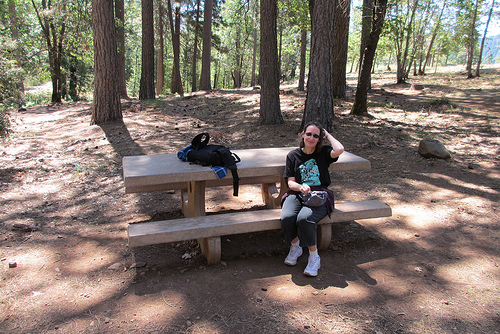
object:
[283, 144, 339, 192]
shirt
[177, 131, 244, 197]
backpack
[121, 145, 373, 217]
table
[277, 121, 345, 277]
woman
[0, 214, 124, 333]
ground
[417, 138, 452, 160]
rock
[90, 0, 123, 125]
trees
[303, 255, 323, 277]
shoes